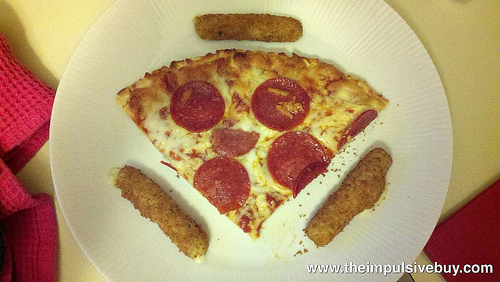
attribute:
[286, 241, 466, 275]
address — web address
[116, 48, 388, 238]
pizza — cheese slice pizza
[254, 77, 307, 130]
pepperoni — large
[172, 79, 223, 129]
pepperoni — large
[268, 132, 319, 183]
pepperoni — large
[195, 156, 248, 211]
pepperoni — large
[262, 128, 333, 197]
pepperoni — bottom-most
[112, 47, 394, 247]
slice — pizza slice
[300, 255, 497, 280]
address — web address, www.theimpulsivebuy.com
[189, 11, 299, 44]
cheese stick — top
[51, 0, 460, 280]
plate — paper, white 